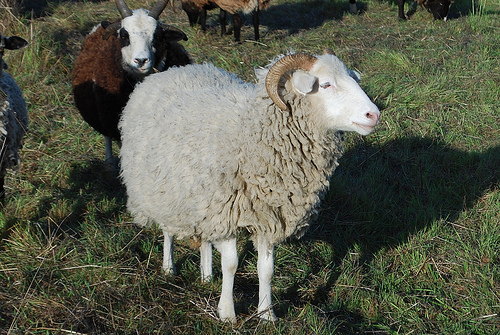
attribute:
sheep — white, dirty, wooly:
[113, 51, 385, 334]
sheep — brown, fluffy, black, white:
[76, 2, 197, 168]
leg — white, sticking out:
[213, 239, 238, 324]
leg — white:
[254, 230, 279, 323]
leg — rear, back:
[158, 230, 175, 275]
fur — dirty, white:
[134, 72, 321, 226]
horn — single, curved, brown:
[263, 54, 316, 106]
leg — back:
[196, 242, 216, 283]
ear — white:
[291, 68, 317, 95]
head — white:
[103, 8, 181, 77]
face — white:
[115, 13, 162, 69]